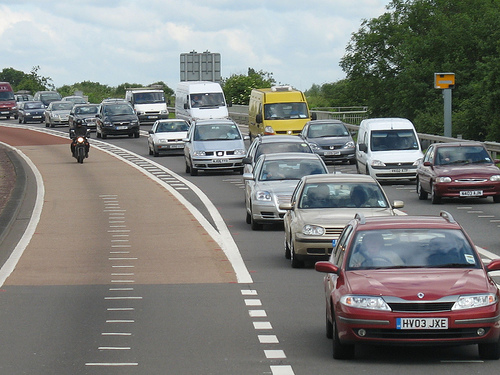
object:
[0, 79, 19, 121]
van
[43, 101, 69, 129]
car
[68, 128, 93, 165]
motorcycle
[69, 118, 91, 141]
man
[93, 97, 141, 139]
van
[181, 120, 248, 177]
van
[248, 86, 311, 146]
van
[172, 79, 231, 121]
van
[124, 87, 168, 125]
van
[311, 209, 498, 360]
car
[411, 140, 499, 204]
car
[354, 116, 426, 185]
van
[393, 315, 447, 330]
license plate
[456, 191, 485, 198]
license plate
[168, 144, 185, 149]
license plate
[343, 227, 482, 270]
windshield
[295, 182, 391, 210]
windshield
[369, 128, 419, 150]
windshield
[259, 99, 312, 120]
windshield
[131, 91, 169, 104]
windshield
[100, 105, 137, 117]
windshield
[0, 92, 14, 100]
windshield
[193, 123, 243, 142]
windshield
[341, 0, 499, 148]
trees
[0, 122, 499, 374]
road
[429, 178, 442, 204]
tire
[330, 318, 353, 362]
tire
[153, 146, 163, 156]
tire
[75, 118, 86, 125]
helmet